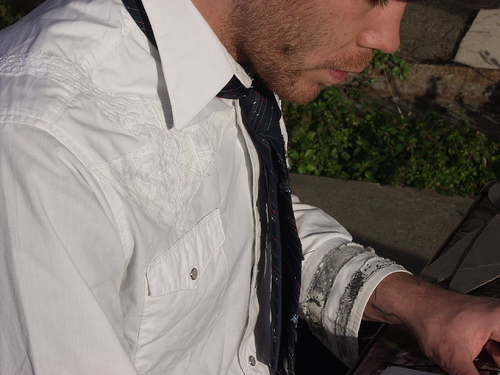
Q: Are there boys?
A: No, there are no boys.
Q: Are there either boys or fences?
A: No, there are no boys or fences.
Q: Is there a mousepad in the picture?
A: No, there are no mouse pads.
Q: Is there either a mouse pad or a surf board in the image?
A: No, there are no mouse pads or surfboards.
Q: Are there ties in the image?
A: Yes, there is a tie.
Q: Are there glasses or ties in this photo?
A: Yes, there is a tie.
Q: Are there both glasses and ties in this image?
A: No, there is a tie but no glasses.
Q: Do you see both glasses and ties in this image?
A: No, there is a tie but no glasses.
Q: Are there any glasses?
A: No, there are no glasses.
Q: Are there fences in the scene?
A: No, there are no fences.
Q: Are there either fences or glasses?
A: No, there are no fences or glasses.